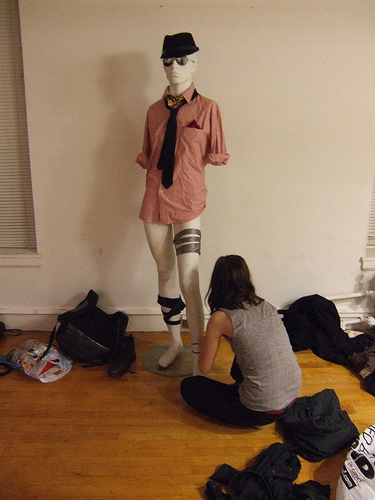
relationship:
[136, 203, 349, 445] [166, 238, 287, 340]
woman has head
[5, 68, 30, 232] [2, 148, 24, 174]
window has blind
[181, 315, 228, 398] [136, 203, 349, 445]
arm of woman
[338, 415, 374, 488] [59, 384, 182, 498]
bag on floor